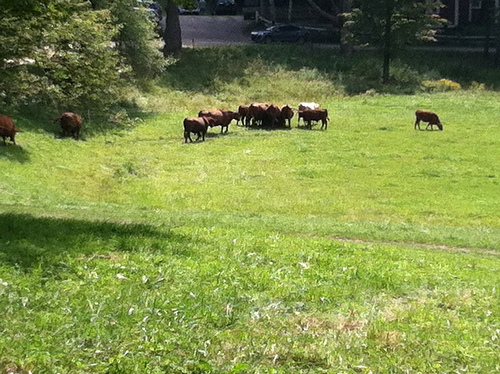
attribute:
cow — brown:
[409, 106, 446, 133]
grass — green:
[360, 86, 499, 188]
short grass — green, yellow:
[9, 91, 498, 371]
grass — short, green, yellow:
[96, 255, 201, 327]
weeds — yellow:
[162, 45, 499, 95]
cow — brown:
[395, 87, 488, 149]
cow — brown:
[288, 79, 343, 130]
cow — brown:
[168, 102, 211, 147]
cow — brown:
[26, 90, 104, 159]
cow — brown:
[0, 100, 33, 144]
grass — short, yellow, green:
[3, 137, 498, 369]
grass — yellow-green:
[133, 166, 476, 331]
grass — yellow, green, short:
[290, 295, 372, 342]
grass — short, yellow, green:
[127, 160, 439, 356]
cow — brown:
[297, 105, 337, 128]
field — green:
[1, 51, 499, 371]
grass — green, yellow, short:
[127, 163, 376, 205]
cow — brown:
[411, 107, 442, 127]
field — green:
[28, 102, 480, 357]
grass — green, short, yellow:
[399, 144, 465, 187]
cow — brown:
[198, 109, 240, 131]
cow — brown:
[57, 109, 92, 139]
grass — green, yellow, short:
[258, 135, 409, 177]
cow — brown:
[301, 109, 322, 126]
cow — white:
[297, 96, 324, 107]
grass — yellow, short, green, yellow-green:
[2, 45, 496, 372]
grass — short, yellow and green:
[437, 290, 468, 312]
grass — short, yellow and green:
[448, 112, 480, 149]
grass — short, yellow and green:
[111, 185, 183, 207]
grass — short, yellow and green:
[135, 227, 177, 244]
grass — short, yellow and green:
[405, 161, 442, 191]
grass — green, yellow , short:
[11, 169, 495, 356]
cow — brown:
[414, 106, 441, 131]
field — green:
[213, 143, 463, 270]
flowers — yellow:
[406, 69, 476, 104]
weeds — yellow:
[392, 61, 492, 99]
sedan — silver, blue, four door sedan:
[247, 19, 314, 46]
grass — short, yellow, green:
[2, 89, 497, 371]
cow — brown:
[413, 104, 460, 140]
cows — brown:
[181, 101, 328, 138]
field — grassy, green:
[2, 0, 499, 371]